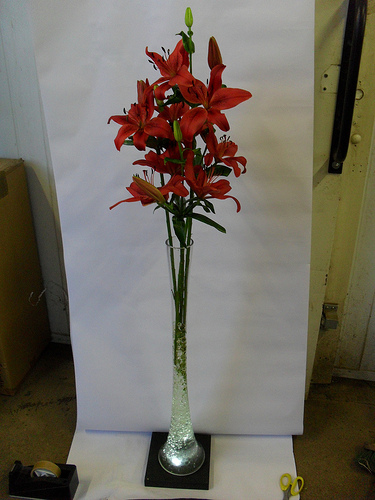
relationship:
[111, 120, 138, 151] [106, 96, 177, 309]
petal on flower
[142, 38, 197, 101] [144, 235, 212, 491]
flower in vase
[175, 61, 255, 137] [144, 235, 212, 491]
flower in vase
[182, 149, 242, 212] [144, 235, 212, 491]
flower in vase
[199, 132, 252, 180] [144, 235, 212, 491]
flower in vase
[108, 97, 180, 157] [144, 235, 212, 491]
flower in vase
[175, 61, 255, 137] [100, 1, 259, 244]
flower in bouquet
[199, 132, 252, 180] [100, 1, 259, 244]
flower in bouquet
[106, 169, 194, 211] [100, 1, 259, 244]
flower in bouquet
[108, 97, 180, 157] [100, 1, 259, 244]
flower in bouquet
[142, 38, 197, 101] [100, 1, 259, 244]
flower in bouquet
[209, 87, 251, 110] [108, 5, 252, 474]
pedal around flower